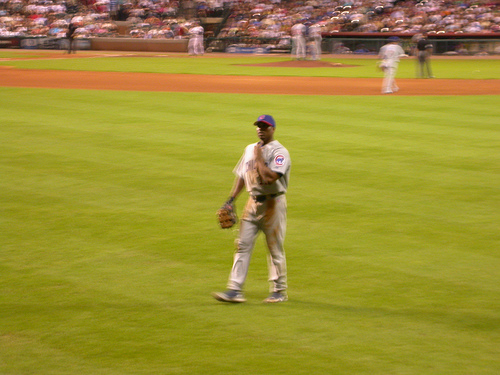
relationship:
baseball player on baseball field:
[212, 114, 293, 309] [0, 41, 498, 373]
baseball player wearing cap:
[212, 114, 291, 303] [251, 109, 281, 133]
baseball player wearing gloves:
[212, 114, 291, 303] [216, 203, 237, 229]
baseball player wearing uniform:
[212, 114, 291, 303] [238, 147, 301, 219]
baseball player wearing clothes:
[212, 114, 291, 303] [416, 36, 435, 73]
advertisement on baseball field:
[227, 41, 279, 65] [24, 54, 494, 354]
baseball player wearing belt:
[212, 114, 291, 303] [245, 185, 285, 200]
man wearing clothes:
[64, 21, 78, 55] [65, 19, 77, 50]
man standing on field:
[64, 21, 78, 55] [1, 47, 497, 374]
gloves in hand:
[212, 207, 237, 231] [221, 196, 238, 229]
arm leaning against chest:
[247, 133, 279, 189] [242, 138, 289, 169]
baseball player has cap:
[212, 114, 291, 303] [254, 113, 276, 127]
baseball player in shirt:
[212, 114, 291, 303] [233, 139, 288, 204]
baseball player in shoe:
[212, 114, 291, 303] [265, 289, 288, 304]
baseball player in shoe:
[212, 114, 291, 303] [213, 290, 246, 307]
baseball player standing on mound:
[290, 18, 308, 61] [238, 41, 330, 82]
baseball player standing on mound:
[308, 21, 326, 60] [238, 41, 330, 82]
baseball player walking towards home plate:
[212, 114, 293, 309] [101, 42, 123, 54]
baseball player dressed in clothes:
[212, 114, 291, 303] [416, 39, 432, 76]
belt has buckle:
[246, 190, 286, 199] [246, 190, 284, 219]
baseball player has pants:
[212, 114, 291, 303] [225, 194, 290, 294]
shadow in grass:
[302, 290, 497, 342] [35, 44, 495, 372]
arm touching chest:
[254, 152, 285, 186] [244, 140, 281, 195]